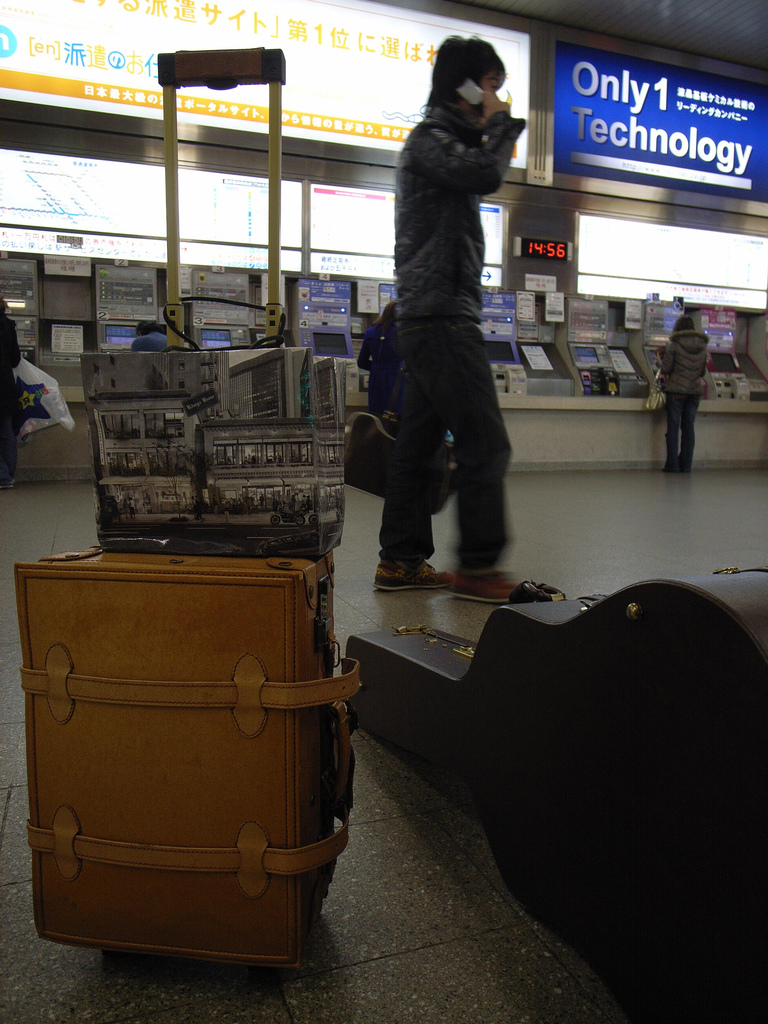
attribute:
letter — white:
[629, 79, 649, 109]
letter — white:
[571, 106, 596, 143]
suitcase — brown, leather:
[11, 548, 365, 965]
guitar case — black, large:
[344, 566, 765, 1021]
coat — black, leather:
[381, 117, 529, 323]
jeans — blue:
[369, 407, 577, 541]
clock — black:
[523, 226, 569, 288]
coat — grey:
[387, 104, 533, 328]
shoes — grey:
[364, 551, 563, 606]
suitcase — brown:
[2, 541, 372, 986]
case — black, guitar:
[346, 576, 764, 1020]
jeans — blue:
[656, 392, 700, 472]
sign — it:
[514, 230, 578, 266]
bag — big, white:
[14, 356, 78, 439]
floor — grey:
[6, 473, 765, 604]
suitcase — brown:
[20, 537, 346, 958]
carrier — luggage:
[101, 43, 343, 565]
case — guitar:
[352, 604, 516, 726]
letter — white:
[567, 54, 597, 107]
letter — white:
[595, 74, 617, 107]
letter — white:
[617, 65, 636, 106]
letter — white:
[623, 82, 656, 118]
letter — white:
[567, 96, 600, 149]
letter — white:
[612, 110, 628, 151]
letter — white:
[645, 115, 667, 159]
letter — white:
[665, 129, 695, 165]